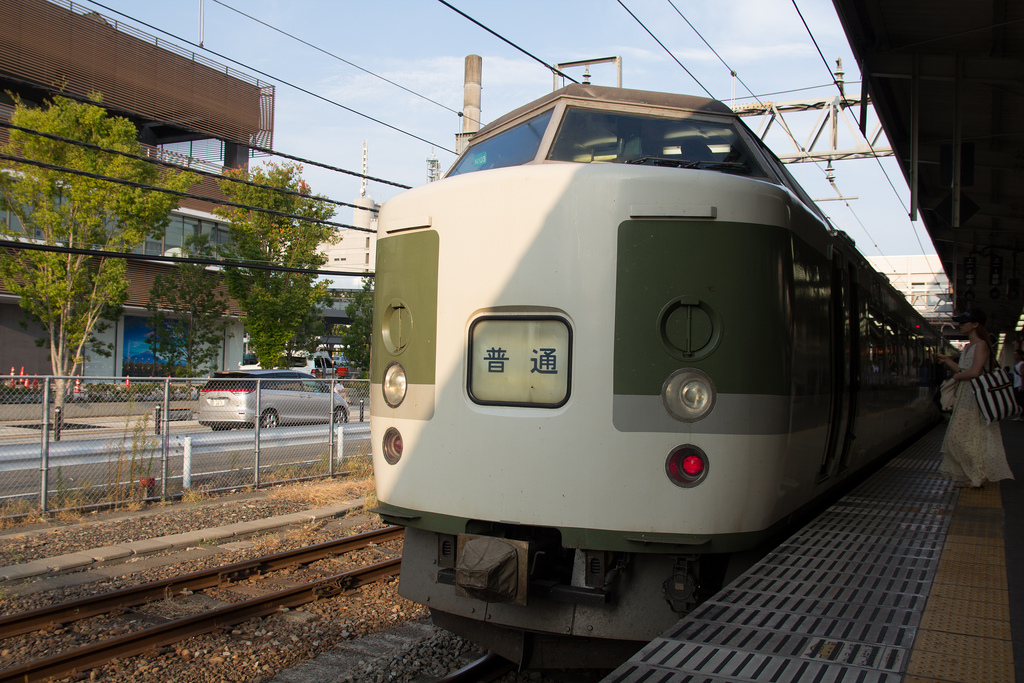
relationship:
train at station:
[364, 80, 969, 679] [575, 1, 1021, 676]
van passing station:
[197, 361, 355, 435] [575, 1, 1021, 676]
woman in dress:
[932, 310, 1015, 485] [939, 338, 1019, 485]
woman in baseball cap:
[932, 305, 1021, 493] [951, 307, 984, 329]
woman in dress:
[932, 305, 1021, 493] [939, 331, 1011, 487]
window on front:
[548, 102, 775, 182] [364, 76, 794, 539]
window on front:
[448, 102, 554, 178] [364, 76, 794, 539]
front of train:
[364, 76, 794, 539] [364, 80, 969, 679]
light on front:
[666, 368, 716, 423] [364, 76, 794, 539]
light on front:
[658, 444, 715, 484] [364, 76, 794, 539]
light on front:
[377, 359, 414, 411] [364, 76, 794, 539]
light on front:
[379, 422, 405, 470] [364, 76, 794, 539]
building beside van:
[0, 1, 279, 395] [197, 364, 353, 429]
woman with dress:
[924, 324, 1013, 446] [924, 365, 1013, 515]